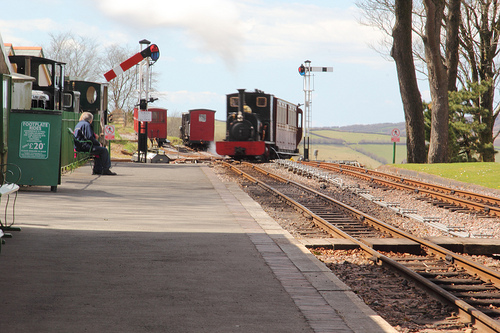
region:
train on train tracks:
[21, 23, 420, 323]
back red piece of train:
[220, 132, 293, 162]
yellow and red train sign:
[85, 31, 170, 86]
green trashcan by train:
[3, 59, 95, 213]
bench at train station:
[38, 91, 125, 187]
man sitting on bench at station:
[59, 104, 116, 183]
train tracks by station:
[265, 134, 407, 323]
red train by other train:
[166, 108, 247, 155]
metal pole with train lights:
[271, 59, 359, 159]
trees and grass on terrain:
[394, 10, 499, 190]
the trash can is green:
[24, 165, 34, 179]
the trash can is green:
[42, 165, 56, 193]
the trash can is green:
[30, 157, 39, 177]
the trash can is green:
[44, 169, 62, 188]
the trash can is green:
[37, 168, 57, 185]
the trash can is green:
[47, 176, 67, 184]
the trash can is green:
[47, 168, 55, 183]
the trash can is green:
[41, 175, 57, 181]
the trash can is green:
[36, 179, 50, 185]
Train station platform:
[0, 16, 265, 320]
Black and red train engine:
[208, 80, 313, 174]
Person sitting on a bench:
[60, 105, 120, 190]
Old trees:
[347, 0, 495, 182]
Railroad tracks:
[232, 144, 490, 294]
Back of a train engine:
[167, 90, 217, 151]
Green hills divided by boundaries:
[306, 115, 413, 163]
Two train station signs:
[95, 20, 340, 164]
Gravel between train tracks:
[250, 165, 496, 305]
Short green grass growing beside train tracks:
[389, 159, 499, 198]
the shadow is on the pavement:
[94, 228, 203, 331]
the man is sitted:
[75, 106, 122, 181]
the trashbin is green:
[13, 111, 64, 193]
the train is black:
[246, 94, 295, 140]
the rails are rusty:
[297, 170, 432, 261]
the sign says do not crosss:
[102, 124, 117, 141]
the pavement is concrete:
[100, 186, 261, 288]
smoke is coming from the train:
[197, 31, 254, 81]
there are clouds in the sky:
[266, 25, 370, 61]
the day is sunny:
[1, 14, 480, 326]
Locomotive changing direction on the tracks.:
[215, 82, 306, 166]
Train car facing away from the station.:
[173, 99, 220, 153]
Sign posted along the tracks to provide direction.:
[385, 122, 405, 162]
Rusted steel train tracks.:
[422, 248, 496, 312]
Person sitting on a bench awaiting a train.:
[67, 108, 119, 179]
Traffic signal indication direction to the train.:
[99, 33, 169, 82]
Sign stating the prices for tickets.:
[15, 116, 54, 162]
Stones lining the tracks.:
[327, 247, 368, 277]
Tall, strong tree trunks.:
[380, 2, 467, 169]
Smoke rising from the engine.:
[190, 15, 244, 82]